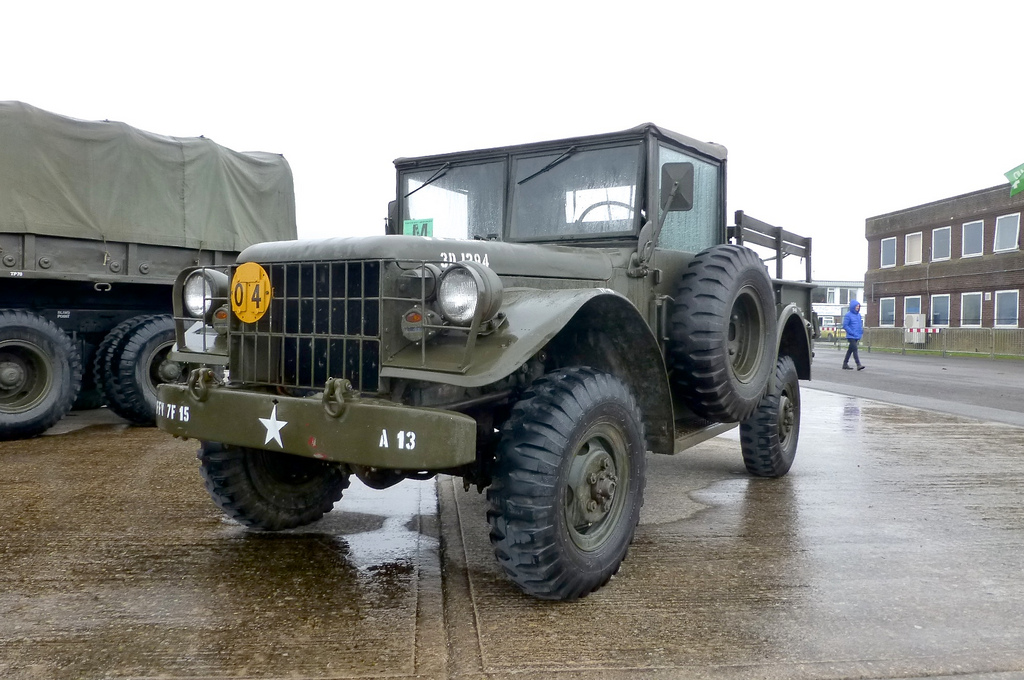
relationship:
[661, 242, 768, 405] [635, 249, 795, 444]
tire on door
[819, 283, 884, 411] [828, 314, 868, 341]
person wearing jacket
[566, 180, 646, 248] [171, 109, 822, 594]
steering wheel in jeep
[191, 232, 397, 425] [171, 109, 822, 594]
front grill on jeep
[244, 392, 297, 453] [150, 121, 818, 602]
star painted on army jeep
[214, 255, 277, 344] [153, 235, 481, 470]
circle attached to front grill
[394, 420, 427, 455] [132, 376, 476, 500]
numbers painted on bumper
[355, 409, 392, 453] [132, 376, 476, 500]
letters painted on bumper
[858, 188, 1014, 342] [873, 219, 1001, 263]
brick building with windows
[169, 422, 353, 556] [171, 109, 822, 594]
wheel of jeep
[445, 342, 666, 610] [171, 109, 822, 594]
wheel of jeep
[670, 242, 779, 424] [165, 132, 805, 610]
tire of jeep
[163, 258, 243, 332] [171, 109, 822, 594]
headlight of jeep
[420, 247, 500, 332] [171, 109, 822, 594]
headlight of jeep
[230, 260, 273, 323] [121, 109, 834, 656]
circle of jeep